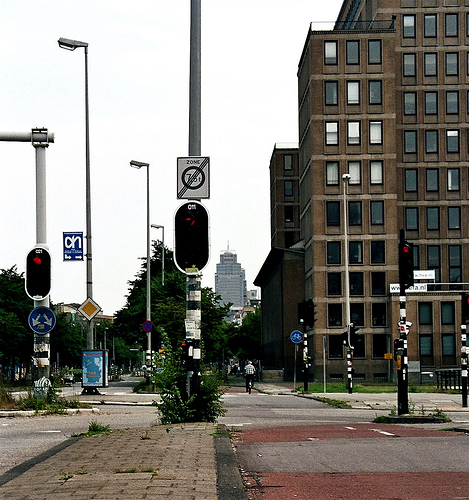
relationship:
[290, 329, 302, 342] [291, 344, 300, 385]
sign on pole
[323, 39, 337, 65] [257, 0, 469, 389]
window adorning city building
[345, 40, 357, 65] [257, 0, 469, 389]
window adorning city building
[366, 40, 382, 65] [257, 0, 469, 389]
window adorning city building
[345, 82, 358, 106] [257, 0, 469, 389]
window adorning city building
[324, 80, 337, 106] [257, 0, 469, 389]
window adorning city building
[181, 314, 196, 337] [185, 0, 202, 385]
poster stuck on pole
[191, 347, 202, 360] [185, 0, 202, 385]
poster stuck on pole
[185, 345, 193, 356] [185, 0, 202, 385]
poster stuck on pole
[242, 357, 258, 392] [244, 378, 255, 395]
person riding bicycle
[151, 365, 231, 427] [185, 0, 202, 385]
green plant growing around pole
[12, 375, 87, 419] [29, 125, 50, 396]
green plant growing around pole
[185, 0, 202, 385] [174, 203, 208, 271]
pole holding black signal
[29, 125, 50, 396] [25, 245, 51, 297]
pole holding black signal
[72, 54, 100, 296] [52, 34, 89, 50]
post with light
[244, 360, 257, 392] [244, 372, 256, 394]
person riding bicycle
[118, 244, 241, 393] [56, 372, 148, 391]
tree on side road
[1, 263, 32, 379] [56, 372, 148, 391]
tree on side road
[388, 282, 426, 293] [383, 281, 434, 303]
sign board displaying business name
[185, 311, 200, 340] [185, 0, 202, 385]
poster on pole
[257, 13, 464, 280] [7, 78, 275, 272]
city building on horizon